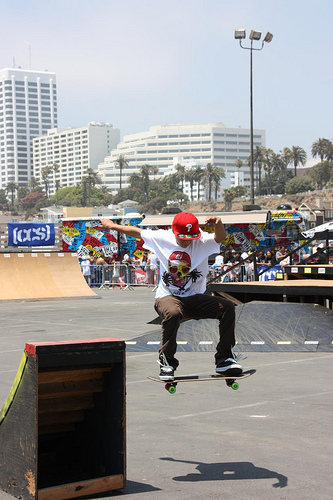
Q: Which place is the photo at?
A: It is at the park.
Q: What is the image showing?
A: It is showing a park.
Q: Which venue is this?
A: This is a park.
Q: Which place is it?
A: It is a park.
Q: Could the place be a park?
A: Yes, it is a park.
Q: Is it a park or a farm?
A: It is a park.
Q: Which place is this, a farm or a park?
A: It is a park.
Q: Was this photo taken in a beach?
A: No, the picture was taken in a park.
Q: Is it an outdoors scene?
A: Yes, it is outdoors.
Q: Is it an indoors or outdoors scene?
A: It is outdoors.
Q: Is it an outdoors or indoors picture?
A: It is outdoors.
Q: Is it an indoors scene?
A: No, it is outdoors.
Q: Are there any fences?
A: Yes, there is a fence.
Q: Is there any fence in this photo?
A: Yes, there is a fence.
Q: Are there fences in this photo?
A: Yes, there is a fence.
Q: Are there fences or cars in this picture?
A: Yes, there is a fence.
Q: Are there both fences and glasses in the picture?
A: No, there is a fence but no glasses.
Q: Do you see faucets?
A: No, there are no faucets.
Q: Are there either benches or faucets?
A: No, there are no faucets or benches.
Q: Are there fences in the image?
A: Yes, there is a fence.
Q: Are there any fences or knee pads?
A: Yes, there is a fence.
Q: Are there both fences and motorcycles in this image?
A: No, there is a fence but no motorcycles.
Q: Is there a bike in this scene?
A: No, there are no bikes.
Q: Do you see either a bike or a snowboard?
A: No, there are no bikes or snowboards.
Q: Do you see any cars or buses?
A: No, there are no cars or buses.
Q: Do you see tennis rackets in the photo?
A: No, there are no tennis rackets.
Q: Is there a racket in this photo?
A: No, there are no rackets.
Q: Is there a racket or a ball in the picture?
A: No, there are no rackets or balls.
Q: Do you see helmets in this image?
A: No, there are no helmets.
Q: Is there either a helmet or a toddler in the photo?
A: No, there are no helmets or toddlers.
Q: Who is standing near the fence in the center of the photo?
A: The spectators are standing near the fence.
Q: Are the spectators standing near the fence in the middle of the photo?
A: Yes, the spectators are standing near the fence.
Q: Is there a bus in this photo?
A: No, there are no buses.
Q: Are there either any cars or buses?
A: No, there are no buses or cars.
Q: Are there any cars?
A: No, there are no cars.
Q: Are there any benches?
A: No, there are no benches.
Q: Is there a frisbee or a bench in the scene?
A: No, there are no benches or frisbees.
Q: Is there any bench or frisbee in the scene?
A: No, there are no benches or frisbees.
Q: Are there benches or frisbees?
A: No, there are no benches or frisbees.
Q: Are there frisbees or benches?
A: No, there are no benches or frisbees.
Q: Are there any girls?
A: No, there are no girls.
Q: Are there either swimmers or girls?
A: No, there are no girls or swimmers.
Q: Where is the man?
A: The man is in the park.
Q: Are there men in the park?
A: Yes, there is a man in the park.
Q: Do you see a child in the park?
A: No, there is a man in the park.